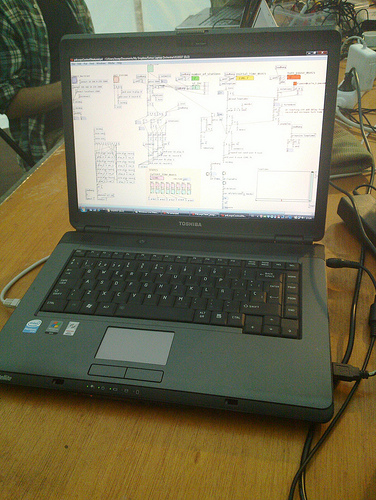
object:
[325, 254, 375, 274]
cable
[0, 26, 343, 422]
laptop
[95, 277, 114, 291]
letters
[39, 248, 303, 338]
keyboard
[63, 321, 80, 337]
stickers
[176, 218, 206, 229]
nameer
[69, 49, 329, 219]
diagram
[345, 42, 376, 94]
powerstrip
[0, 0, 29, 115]
sleeve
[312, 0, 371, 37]
wires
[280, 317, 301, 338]
button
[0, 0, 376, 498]
desk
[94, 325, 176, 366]
mousepad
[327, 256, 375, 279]
cord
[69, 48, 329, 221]
screen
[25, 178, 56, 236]
wooden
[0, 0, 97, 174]
person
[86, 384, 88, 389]
lights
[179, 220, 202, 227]
brand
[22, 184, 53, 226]
woodgrain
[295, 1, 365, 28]
cables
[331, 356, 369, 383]
black cable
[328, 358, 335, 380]
usbport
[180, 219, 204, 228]
computercompany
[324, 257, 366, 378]
blackcords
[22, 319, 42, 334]
brand stickers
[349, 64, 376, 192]
cords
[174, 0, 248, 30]
laptop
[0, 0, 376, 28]
background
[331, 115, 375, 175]
clothing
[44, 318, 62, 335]
logos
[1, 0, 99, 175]
plaidshirt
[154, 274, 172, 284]
keys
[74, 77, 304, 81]
boxes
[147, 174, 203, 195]
bluepattern